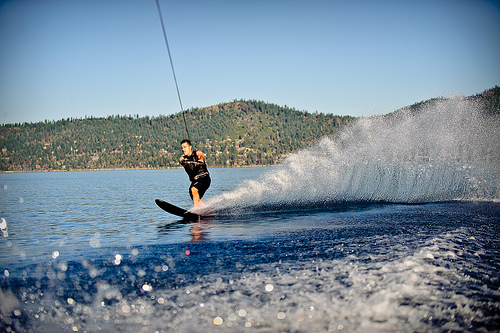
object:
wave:
[186, 185, 499, 217]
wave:
[0, 223, 499, 332]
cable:
[153, 0, 193, 147]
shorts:
[188, 173, 213, 198]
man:
[175, 139, 212, 210]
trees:
[0, 86, 499, 170]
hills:
[0, 85, 499, 172]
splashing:
[186, 90, 499, 217]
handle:
[179, 157, 201, 165]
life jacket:
[176, 149, 209, 181]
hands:
[193, 156, 205, 163]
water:
[0, 165, 499, 331]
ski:
[154, 197, 226, 220]